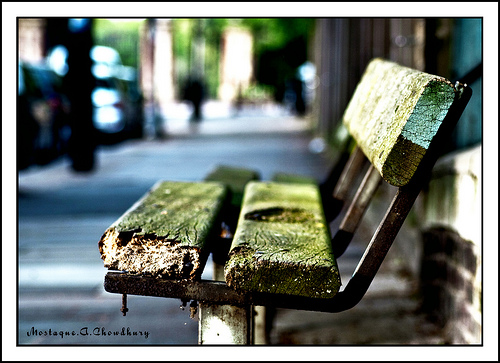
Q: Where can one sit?
A: Bench.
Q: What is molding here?
A: Bench.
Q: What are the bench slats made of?
A: Wood.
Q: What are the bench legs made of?
A: Metal.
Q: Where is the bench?
A: On the sidewalk.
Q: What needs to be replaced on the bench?
A: The first seat slat.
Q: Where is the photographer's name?
A: On the bottom left.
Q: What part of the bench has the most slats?
A: The bottom.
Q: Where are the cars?
A: On the side of the road.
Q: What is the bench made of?
A: Wood.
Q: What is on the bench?
A: Nothing.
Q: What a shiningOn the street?
A: The sun is shining.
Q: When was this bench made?
A: Long ago.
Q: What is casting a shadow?
A: The bench.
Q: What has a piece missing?
A: The bench.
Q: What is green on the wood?
A: Mold.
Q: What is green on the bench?
A: Dark greenMold.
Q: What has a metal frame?
A: The green bench.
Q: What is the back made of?
A: Wood and metal.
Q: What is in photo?
A: A bench.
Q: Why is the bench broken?
A: It is old.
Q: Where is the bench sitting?
A: Sidewalk.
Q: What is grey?
A: Ground.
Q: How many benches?
A: One.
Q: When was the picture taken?
A: Daytime.